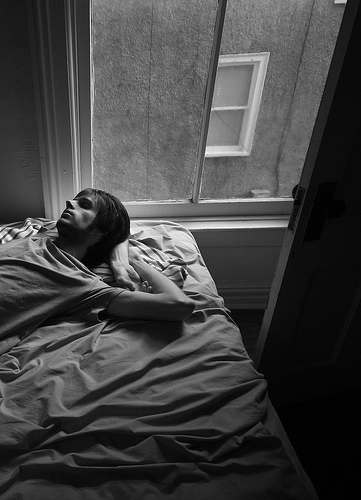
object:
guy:
[1, 186, 196, 323]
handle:
[303, 176, 334, 242]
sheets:
[0, 216, 317, 498]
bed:
[1, 216, 320, 498]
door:
[253, 1, 360, 406]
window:
[71, 0, 346, 214]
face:
[57, 191, 98, 228]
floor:
[230, 300, 359, 499]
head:
[52, 183, 129, 262]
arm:
[92, 249, 197, 321]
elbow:
[159, 282, 196, 319]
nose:
[65, 197, 76, 208]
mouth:
[61, 207, 75, 220]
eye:
[76, 199, 92, 210]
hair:
[76, 186, 130, 254]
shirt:
[0, 234, 126, 361]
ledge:
[127, 199, 295, 231]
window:
[198, 50, 271, 157]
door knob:
[290, 179, 308, 201]